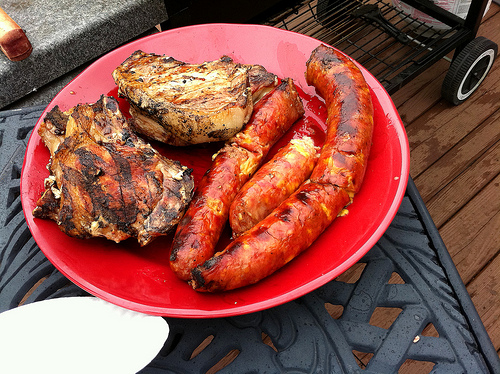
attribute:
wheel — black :
[440, 35, 497, 107]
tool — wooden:
[0, 27, 41, 72]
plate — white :
[4, 273, 183, 369]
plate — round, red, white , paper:
[12, 19, 410, 321]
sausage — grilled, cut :
[231, 114, 321, 236]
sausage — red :
[178, 40, 376, 290]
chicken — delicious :
[30, 97, 193, 239]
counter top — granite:
[0, 0, 169, 110]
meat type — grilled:
[37, 93, 191, 245]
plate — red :
[216, 29, 303, 80]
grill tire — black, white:
[441, 35, 498, 106]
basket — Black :
[263, 1, 466, 93]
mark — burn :
[188, 256, 219, 295]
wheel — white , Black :
[440, 30, 498, 109]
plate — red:
[213, 22, 283, 51]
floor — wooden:
[275, 6, 498, 372]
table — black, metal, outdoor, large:
[2, 105, 497, 371]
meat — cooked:
[30, 92, 202, 245]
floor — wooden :
[178, 5, 499, 372]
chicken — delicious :
[126, 33, 250, 155]